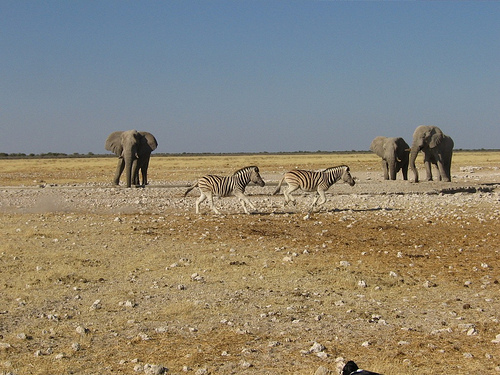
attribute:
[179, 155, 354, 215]
zebras — running, galloping, black, white, free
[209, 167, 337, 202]
stripes — brown, black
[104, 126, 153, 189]
elephant — large, gray, young, big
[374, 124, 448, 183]
elephants — large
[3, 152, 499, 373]
desert — very dry, rocky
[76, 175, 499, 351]
rocks — white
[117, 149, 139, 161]
tusks — white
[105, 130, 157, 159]
ears — large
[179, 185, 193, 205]
tail — black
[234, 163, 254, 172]
mane — black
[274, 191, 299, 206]
legs — airborne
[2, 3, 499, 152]
sky — blue, clear